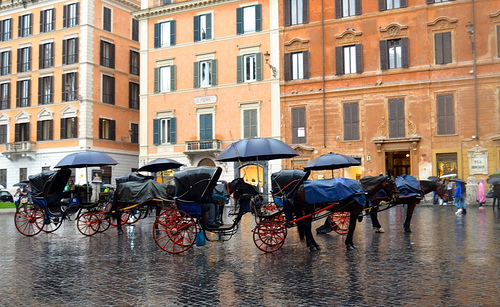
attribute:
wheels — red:
[153, 207, 205, 252]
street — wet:
[2, 197, 499, 304]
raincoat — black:
[113, 178, 169, 207]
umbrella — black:
[305, 148, 357, 170]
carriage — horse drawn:
[152, 166, 297, 253]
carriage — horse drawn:
[15, 160, 115, 239]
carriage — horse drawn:
[110, 164, 184, 223]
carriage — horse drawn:
[221, 161, 295, 232]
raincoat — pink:
[469, 173, 499, 201]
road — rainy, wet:
[4, 219, 499, 301]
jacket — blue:
[306, 174, 368, 209]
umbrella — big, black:
[219, 136, 294, 164]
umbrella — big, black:
[54, 149, 116, 169]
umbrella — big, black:
[303, 149, 358, 179]